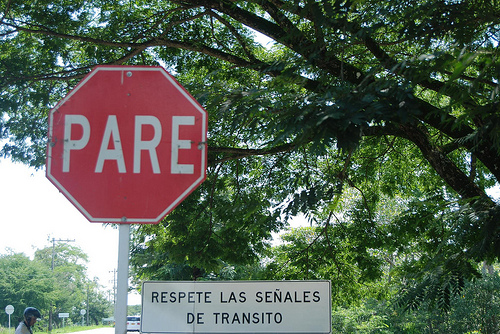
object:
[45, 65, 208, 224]
sign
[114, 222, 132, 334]
pole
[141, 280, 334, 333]
sign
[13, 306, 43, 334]
man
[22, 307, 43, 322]
helmet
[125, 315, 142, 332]
car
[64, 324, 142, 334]
road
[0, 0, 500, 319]
tree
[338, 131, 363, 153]
leaves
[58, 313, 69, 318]
sign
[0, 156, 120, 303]
sky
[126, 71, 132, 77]
bolt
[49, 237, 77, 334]
pole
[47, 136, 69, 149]
dirt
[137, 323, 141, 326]
lights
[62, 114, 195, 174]
pare